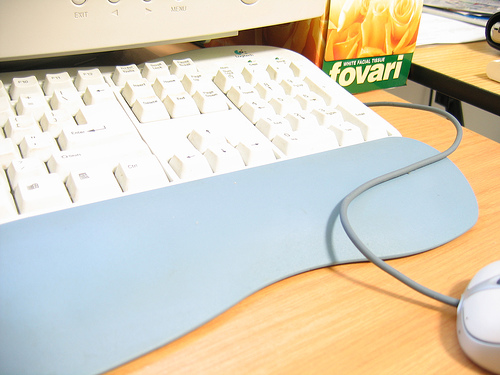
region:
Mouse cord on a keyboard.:
[340, 100, 463, 320]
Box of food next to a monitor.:
[270, 2, 417, 89]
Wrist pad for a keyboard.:
[2, 140, 476, 372]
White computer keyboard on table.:
[0, 42, 393, 217]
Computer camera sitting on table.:
[475, 13, 498, 83]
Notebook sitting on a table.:
[415, 4, 488, 52]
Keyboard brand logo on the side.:
[230, 48, 248, 58]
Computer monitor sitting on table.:
[2, 1, 339, 66]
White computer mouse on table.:
[452, 264, 497, 370]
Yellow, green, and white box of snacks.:
[266, 10, 431, 90]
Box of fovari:
[262, 3, 417, 86]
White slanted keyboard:
[11, 78, 410, 360]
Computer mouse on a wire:
[316, 90, 498, 365]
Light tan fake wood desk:
[170, 97, 488, 372]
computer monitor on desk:
[2, 1, 337, 62]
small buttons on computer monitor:
[66, 0, 289, 10]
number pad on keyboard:
[211, 52, 387, 154]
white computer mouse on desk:
[452, 257, 499, 370]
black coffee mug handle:
[482, 4, 497, 58]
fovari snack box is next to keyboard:
[276, 3, 416, 103]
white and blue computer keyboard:
[4, 37, 441, 371]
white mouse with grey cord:
[335, 93, 495, 370]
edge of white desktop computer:
[1, 0, 326, 71]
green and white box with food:
[297, 0, 432, 101]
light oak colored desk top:
[103, 82, 498, 372]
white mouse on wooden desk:
[443, 265, 498, 364]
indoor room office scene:
[5, 15, 494, 370]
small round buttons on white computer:
[68, 0, 264, 17]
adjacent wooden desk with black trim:
[414, 0, 499, 122]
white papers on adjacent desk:
[418, 6, 488, 56]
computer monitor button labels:
[0, 0, 315, 50]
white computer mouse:
[445, 240, 495, 360]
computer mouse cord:
[340, 90, 495, 350]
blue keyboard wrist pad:
[5, 150, 451, 270]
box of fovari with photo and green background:
[275, 0, 430, 85]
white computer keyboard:
[1, 45, 476, 300]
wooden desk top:
[10, 61, 497, 368]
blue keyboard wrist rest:
[2, 125, 473, 350]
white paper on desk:
[385, 0, 493, 45]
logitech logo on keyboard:
[224, 44, 259, 62]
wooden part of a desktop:
[317, 314, 389, 366]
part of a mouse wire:
[385, 255, 447, 328]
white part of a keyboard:
[71, 95, 209, 187]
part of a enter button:
[56, 108, 111, 138]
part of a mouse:
[463, 287, 496, 328]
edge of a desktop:
[437, 82, 483, 112]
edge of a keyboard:
[248, 260, 303, 297]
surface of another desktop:
[444, 32, 484, 75]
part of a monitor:
[92, 8, 161, 43]